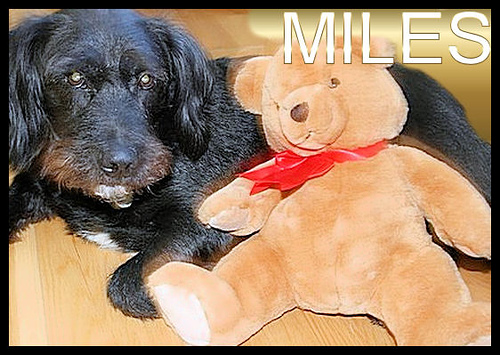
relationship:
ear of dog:
[8, 10, 62, 175] [5, 10, 484, 320]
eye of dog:
[60, 70, 88, 89] [5, 10, 484, 320]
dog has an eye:
[5, 10, 484, 320] [64, 71, 85, 87]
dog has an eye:
[5, 10, 484, 320] [133, 73, 153, 93]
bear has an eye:
[137, 42, 491, 351] [270, 98, 286, 114]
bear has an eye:
[137, 42, 491, 351] [326, 78, 344, 92]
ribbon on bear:
[234, 136, 400, 198] [137, 36, 499, 347]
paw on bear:
[194, 174, 278, 239] [137, 36, 499, 347]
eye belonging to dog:
[60, 70, 88, 89] [5, 10, 484, 320]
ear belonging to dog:
[142, 7, 218, 162] [5, 10, 484, 320]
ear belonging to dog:
[8, 10, 62, 175] [5, 10, 484, 320]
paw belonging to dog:
[104, 251, 169, 321] [5, 10, 484, 320]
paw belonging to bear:
[104, 263, 165, 321] [137, 36, 499, 347]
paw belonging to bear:
[402, 300, 484, 345] [137, 36, 499, 347]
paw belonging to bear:
[194, 181, 276, 239] [137, 36, 499, 347]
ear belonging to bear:
[232, 55, 272, 116] [137, 36, 499, 347]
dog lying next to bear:
[5, 10, 484, 320] [137, 36, 499, 347]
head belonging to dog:
[32, 9, 175, 212] [5, 10, 484, 320]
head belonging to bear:
[257, 40, 410, 159] [137, 36, 499, 347]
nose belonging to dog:
[96, 142, 140, 179] [5, 10, 484, 320]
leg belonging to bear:
[143, 232, 294, 345] [137, 36, 499, 347]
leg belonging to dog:
[103, 203, 243, 322] [5, 10, 484, 320]